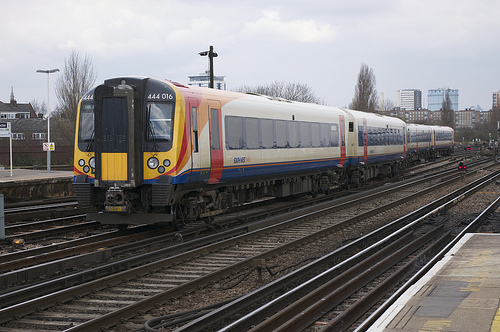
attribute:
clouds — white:
[240, 11, 335, 50]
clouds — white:
[74, 10, 166, 49]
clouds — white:
[239, 1, 387, 71]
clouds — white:
[242, 14, 338, 64]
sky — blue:
[2, 14, 497, 142]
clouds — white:
[241, 8, 340, 50]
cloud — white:
[239, 12, 344, 44]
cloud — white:
[0, 4, 170, 99]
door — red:
[205, 97, 227, 189]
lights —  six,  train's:
[78, 154, 170, 181]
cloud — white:
[237, 7, 334, 50]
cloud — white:
[104, 7, 164, 41]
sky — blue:
[2, 0, 497, 42]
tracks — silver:
[186, 197, 423, 328]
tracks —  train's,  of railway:
[0, 149, 497, 329]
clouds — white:
[243, 11, 498, 58]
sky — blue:
[2, 2, 499, 118]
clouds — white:
[0, 0, 500, 82]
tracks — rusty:
[174, 165, 499, 330]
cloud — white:
[345, 2, 498, 67]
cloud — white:
[230, 4, 343, 50]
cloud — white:
[2, 2, 232, 66]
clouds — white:
[317, 10, 447, 61]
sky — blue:
[1, 3, 496, 89]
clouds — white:
[22, 9, 345, 54]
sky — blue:
[2, 2, 492, 102]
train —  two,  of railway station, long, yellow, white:
[67, 65, 467, 222]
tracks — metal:
[36, 155, 498, 330]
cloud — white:
[240, 6, 340, 46]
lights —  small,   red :
[454, 159, 468, 181]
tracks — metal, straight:
[295, 205, 450, 271]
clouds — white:
[246, 16, 344, 89]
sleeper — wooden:
[141, 272, 189, 284]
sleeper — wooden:
[111, 284, 164, 292]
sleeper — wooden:
[38, 307, 100, 322]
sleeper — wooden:
[230, 246, 270, 251]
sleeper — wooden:
[203, 252, 248, 262]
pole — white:
[37, 67, 57, 169]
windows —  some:
[218, 112, 243, 151]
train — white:
[73, 78, 461, 215]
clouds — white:
[286, 17, 338, 46]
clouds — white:
[261, 7, 283, 21]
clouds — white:
[236, 13, 288, 43]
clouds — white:
[163, 29, 201, 55]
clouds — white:
[190, 15, 245, 38]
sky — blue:
[2, 0, 492, 173]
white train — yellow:
[71, 75, 455, 228]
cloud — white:
[6, 0, 373, 94]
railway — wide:
[3, 178, 497, 326]